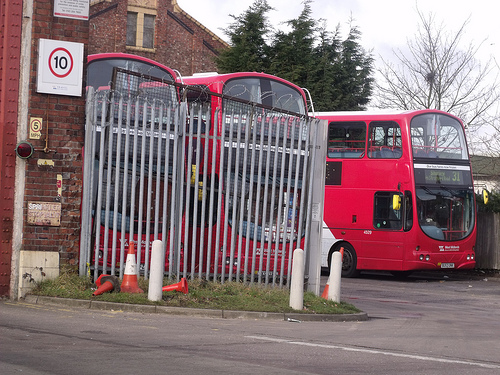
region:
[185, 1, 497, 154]
cloud cover in sky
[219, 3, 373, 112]
tops of green trees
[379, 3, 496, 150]
tree with no leaves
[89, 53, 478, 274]
three double decker busses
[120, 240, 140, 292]
white and orange pylon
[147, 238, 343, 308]
three white posts in grass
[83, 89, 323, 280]
metal poles of fence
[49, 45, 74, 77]
number in red circle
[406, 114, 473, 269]
windows on front of bus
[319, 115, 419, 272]
side of red and white bus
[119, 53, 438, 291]
red double decker buses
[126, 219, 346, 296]
white posts near fence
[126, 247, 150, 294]
orange and white cones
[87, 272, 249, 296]
cones on ground near fence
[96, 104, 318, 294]
grey posts in fence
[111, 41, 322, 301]
two buses behind fence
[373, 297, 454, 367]
parking lot is grey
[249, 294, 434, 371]
white lines in parking lot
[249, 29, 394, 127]
green tree behind buses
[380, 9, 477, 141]
bare tree in distance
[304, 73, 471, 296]
red bus not behind gate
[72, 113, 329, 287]
metal gates in front of buses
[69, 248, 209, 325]
three orange cones in front of gate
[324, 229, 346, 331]
single orange cone behind pole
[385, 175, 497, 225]
yellow side mirrors on bus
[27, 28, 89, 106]
white red and black sign with 10 circled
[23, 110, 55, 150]
white red and black sign with 5 circled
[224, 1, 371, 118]
group of cedar trees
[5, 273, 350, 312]
grassy median in front of gates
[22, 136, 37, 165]
red reflective caution light on left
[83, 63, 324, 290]
Metal fencing with barbed wire on top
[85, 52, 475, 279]
Three red double-decker buses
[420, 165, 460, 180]
Sign on bus indicating route number 31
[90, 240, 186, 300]
Three orange safety cones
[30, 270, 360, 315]
Small patch of grass beside a building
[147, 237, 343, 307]
Four white circular concrete posts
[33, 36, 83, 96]
White sign with the number 10 in a red circle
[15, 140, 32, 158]
Red light attached to side of building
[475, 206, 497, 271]
Small portion of a wooden fence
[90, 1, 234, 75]
Red brick building behind the buses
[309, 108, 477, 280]
a red double decker bus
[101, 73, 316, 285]
a red double decker bus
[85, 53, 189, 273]
a red double decker bus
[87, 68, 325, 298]
a tall metal fence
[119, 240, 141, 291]
an orange and white traffic cone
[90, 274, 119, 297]
an orange traffic cone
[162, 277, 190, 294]
an orange traffic cone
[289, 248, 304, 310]
a white concrete pole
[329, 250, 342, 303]
a white concrete pole